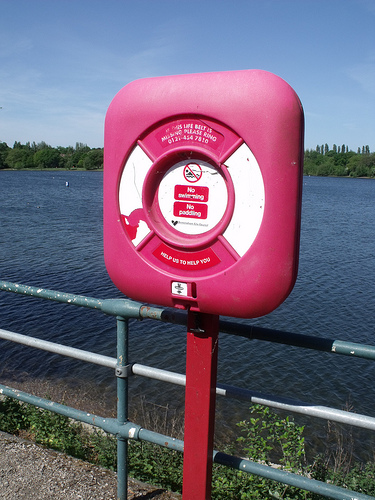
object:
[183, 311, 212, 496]
stand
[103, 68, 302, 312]
sign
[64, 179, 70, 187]
buoy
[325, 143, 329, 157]
tree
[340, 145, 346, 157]
tree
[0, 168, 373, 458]
water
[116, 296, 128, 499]
pole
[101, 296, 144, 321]
attachment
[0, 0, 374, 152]
sky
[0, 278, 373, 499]
handrails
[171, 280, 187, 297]
label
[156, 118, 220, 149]
letters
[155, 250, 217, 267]
writing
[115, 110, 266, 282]
diagram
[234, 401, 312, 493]
weeds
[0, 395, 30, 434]
plant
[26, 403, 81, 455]
plant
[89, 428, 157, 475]
plant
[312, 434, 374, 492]
plant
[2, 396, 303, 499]
ground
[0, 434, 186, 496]
gravel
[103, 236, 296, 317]
bottom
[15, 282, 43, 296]
paint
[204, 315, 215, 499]
edge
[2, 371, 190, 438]
grass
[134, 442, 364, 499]
bank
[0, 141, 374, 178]
area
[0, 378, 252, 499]
edge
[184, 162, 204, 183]
no swimming